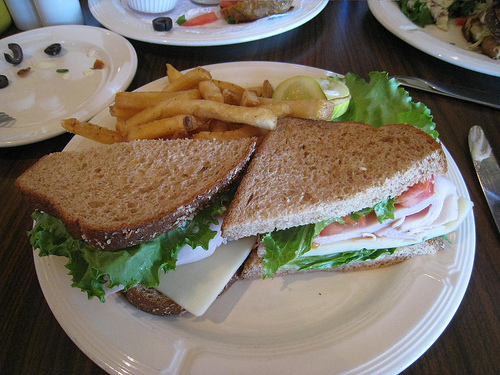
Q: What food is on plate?
A: Sandwich and fries.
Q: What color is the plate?
A: White.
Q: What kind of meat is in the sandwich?
A: Turkey.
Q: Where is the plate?
A: On table.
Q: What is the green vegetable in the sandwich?
A: Lettuce.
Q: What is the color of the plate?
A: White.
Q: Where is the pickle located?
A: Behind the sandwich.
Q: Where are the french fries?
A: At the back of the plate.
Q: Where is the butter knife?
A: On the table.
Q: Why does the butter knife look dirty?
A: Because it was used.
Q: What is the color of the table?
A: Brown.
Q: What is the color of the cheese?
A: White.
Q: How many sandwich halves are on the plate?
A: Two.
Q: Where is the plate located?
A: On the table.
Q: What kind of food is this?
A: Sandwich.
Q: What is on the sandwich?
A: Cheese , meat and lettuce.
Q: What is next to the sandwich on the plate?
A: French fries.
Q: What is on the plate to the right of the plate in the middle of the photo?
A: Salad.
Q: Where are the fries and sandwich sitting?
A: Plate.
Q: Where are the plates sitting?
A: Table.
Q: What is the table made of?
A: Wood.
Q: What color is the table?
A: Brown.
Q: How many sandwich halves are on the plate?
A: Two.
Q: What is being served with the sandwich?
A: Fries.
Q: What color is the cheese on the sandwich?
A: White.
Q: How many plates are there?
A: 4.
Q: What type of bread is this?
A: Wheat bread.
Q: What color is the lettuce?
A: Green.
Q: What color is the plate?
A: White.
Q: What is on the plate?
A: A sandwich.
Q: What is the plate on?
A: A table.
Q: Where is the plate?
A: On the table.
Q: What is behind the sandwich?
A: Fries.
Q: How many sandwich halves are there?
A: Two.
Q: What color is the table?
A: Brown.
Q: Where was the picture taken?
A: At a restaurant.